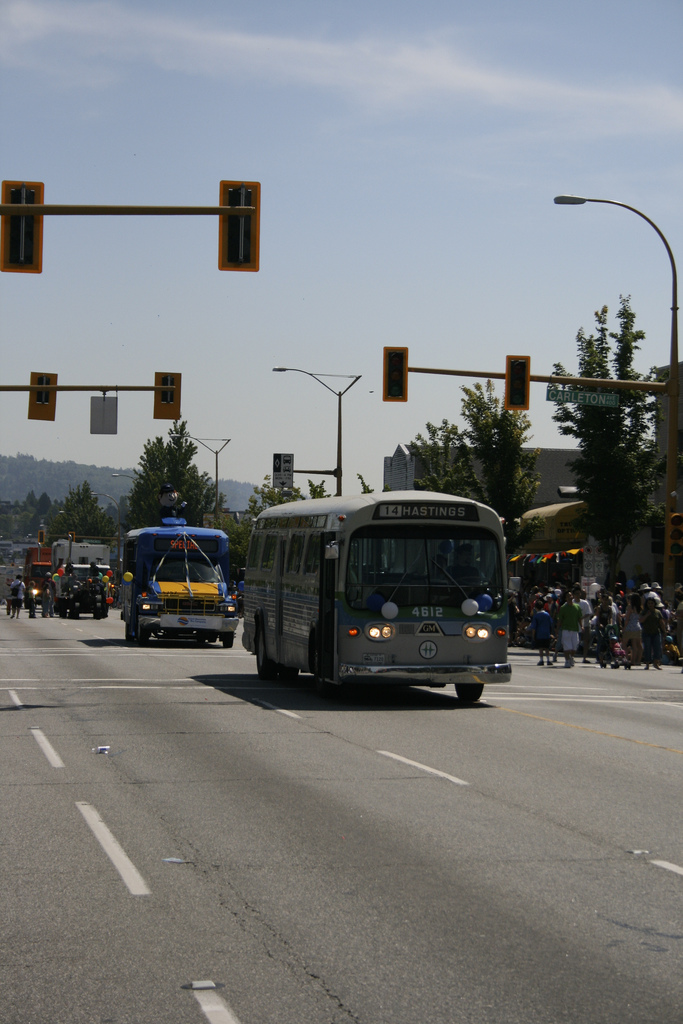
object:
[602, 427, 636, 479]
leaves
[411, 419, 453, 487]
leaves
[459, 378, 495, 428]
leaves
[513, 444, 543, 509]
leaves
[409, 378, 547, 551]
tree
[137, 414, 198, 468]
leaves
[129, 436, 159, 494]
leaves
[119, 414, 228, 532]
tree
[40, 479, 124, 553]
tree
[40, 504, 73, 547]
leaves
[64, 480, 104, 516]
leaves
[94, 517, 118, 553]
leaves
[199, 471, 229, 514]
leaves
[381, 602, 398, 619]
ballon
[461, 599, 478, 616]
ballon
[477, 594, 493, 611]
ballon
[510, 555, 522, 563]
flag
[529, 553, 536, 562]
flag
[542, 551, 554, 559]
flag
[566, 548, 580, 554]
flag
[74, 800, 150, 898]
stripe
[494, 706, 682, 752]
line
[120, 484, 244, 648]
bus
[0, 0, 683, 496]
cloud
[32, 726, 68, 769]
lines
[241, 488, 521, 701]
bus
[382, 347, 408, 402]
lights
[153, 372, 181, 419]
lights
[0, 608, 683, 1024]
road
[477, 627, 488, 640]
head light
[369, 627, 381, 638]
head light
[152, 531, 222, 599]
streamer